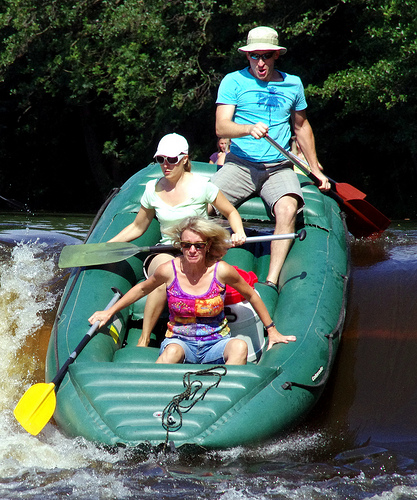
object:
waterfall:
[347, 260, 417, 434]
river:
[0, 458, 416, 500]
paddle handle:
[57, 283, 124, 387]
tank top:
[160, 259, 233, 341]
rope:
[156, 362, 229, 441]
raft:
[42, 159, 352, 457]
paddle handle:
[260, 133, 330, 196]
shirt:
[214, 66, 312, 173]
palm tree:
[254, 84, 287, 131]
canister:
[222, 296, 266, 366]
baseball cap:
[153, 128, 190, 166]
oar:
[8, 284, 124, 443]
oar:
[54, 227, 311, 274]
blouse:
[137, 171, 223, 246]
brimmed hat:
[233, 20, 289, 54]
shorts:
[207, 154, 308, 218]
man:
[208, 21, 333, 322]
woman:
[102, 129, 248, 252]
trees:
[0, 0, 413, 135]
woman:
[84, 214, 298, 365]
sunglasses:
[155, 154, 184, 167]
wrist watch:
[261, 320, 277, 335]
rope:
[277, 206, 352, 396]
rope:
[50, 181, 122, 374]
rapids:
[0, 232, 48, 498]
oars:
[252, 124, 395, 254]